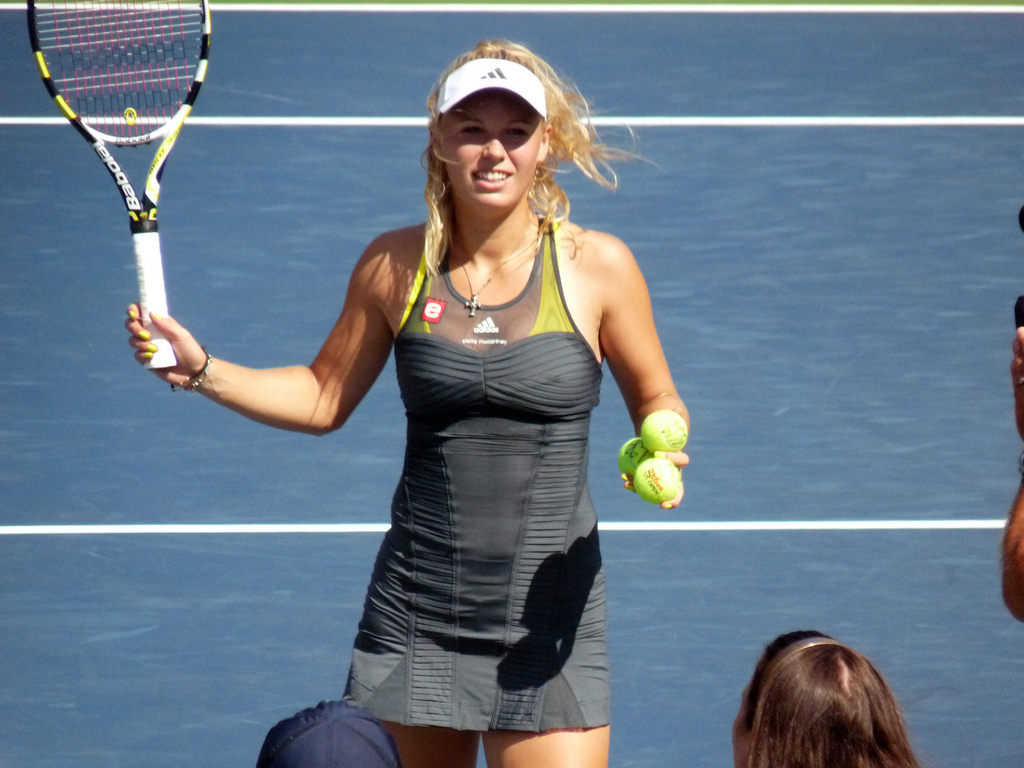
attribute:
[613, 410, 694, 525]
balls — green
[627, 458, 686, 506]
tennis ball — yellow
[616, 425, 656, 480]
tennis ball — yellow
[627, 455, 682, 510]
tennis ball — yellow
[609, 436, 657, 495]
tennis ball — yellow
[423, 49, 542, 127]
visor — white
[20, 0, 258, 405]
tennis racket — red, black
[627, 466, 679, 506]
tennis ball — green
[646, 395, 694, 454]
tennis ball — green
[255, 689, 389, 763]
hat — blue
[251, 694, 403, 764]
cap — blue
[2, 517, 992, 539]
marking — white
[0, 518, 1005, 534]
line — white 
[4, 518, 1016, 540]
line — white 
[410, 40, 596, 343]
hair — blonde 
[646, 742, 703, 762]
paw — dog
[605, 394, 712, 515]
hand — player 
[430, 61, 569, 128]
visor — white 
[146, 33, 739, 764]
woman —  dark gray outfit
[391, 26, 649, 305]
hair —  blonde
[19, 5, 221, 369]
racket — black and white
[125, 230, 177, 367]
handle — white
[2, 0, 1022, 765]
tennis court — blue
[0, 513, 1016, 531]
line — white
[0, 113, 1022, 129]
line — white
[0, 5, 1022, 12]
line — white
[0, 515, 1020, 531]
line — white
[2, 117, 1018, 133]
line — white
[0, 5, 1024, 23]
line — white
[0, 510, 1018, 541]
tennis court — blue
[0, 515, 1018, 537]
line — white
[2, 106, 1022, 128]
line — white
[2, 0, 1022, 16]
line — white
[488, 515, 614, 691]
shadow — black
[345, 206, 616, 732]
outfit — gray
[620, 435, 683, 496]
tennis ball — green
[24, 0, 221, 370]
tennis racket — yellow, black, and white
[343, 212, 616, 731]
tennis dress — black and yellow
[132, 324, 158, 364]
fingernails — yellow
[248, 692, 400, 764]
baseball cap — blue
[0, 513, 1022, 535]
stripe — white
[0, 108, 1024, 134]
stripe — white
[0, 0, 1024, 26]
stripe — white